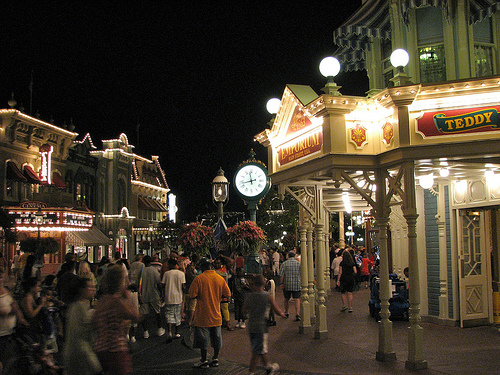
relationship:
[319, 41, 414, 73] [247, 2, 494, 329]
lights on top of building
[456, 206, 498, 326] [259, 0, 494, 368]
door on building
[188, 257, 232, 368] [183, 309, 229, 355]
man wearing blue shorts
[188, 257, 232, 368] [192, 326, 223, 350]
man wearing blue shorts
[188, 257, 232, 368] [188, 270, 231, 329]
man wearing yellow shirt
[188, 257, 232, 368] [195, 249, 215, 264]
man wearing hat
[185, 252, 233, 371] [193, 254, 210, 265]
man has on hat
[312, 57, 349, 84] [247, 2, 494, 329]
light on building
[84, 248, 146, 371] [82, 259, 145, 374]
person with clothes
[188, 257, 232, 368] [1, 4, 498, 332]
man in town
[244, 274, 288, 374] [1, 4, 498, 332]
people in town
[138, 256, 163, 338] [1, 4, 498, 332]
man in town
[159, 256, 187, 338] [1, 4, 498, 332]
person in town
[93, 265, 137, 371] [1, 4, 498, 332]
person in town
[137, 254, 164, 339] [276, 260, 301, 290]
man with a blue shirt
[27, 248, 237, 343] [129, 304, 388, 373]
people in street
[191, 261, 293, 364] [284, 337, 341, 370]
people at street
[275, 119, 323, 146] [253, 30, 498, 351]
lights illuminated from stores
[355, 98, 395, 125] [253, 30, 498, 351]
lights illuminated from stores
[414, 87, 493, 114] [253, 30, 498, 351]
lights illuminated from stores